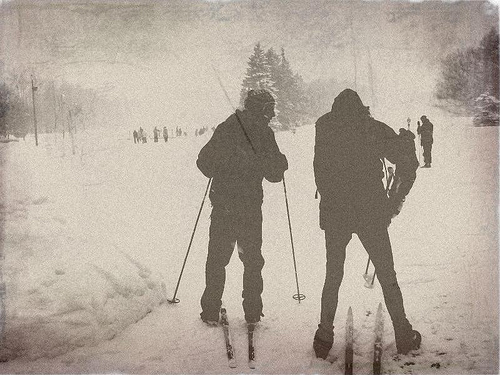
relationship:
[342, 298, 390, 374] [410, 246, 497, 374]
skis covered in snow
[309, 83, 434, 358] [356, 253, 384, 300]
person holding ski poles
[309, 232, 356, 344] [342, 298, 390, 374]
leg over skis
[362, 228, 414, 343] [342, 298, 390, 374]
leg over skis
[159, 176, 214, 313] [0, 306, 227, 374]
ski pole in snow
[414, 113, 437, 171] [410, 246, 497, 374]
man in snow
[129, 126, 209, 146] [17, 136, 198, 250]
people standing in snow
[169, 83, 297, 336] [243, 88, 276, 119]
man wearing hat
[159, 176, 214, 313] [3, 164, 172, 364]
ski pole next to snow bank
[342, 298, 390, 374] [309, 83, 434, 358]
skis beneath man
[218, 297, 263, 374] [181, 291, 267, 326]
skis on feet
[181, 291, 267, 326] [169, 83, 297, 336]
feet of man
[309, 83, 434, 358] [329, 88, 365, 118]
man wearing hood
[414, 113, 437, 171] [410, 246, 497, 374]
man standing in snow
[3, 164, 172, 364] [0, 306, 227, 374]
mound of snow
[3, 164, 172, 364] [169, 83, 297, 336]
mound by man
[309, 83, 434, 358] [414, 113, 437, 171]
mound by man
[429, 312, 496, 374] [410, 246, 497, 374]
marks in snow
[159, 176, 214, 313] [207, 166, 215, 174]
ski pole in hand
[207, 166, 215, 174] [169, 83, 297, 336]
hand of man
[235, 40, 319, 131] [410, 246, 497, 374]
trees covered in snow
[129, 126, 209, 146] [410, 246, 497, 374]
people skiing on snow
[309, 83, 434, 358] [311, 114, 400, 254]
male has back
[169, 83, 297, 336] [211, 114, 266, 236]
male has back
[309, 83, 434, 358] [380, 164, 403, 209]
male holding ski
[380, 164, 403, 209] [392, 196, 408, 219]
ski in hand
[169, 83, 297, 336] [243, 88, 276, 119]
male wearing hat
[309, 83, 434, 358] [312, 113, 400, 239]
male wearing jacket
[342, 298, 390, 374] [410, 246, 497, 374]
skis on snow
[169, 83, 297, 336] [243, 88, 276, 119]
skier wearing hat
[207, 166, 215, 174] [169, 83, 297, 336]
hand of person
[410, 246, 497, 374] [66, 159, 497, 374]
snow on ground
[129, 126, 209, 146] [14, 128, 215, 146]
people in background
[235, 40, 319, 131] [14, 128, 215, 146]
trees in background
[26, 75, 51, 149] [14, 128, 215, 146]
pole in background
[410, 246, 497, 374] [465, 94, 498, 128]
snow on bush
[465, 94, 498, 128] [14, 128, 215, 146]
bush in background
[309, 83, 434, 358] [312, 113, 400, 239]
person wearing jacket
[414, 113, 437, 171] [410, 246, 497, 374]
man on snow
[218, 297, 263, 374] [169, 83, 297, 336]
skis below man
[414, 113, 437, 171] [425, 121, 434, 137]
man wears cloth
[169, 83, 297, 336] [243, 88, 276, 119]
man wears cap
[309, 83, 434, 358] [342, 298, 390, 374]
person holding skis